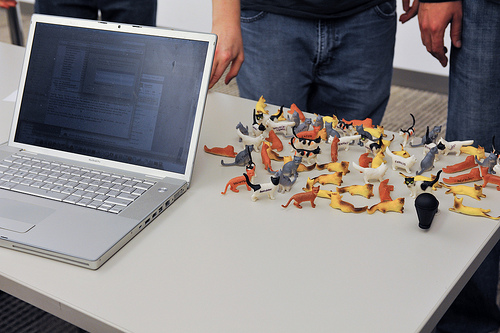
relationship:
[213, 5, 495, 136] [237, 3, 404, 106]
two people wearing jeans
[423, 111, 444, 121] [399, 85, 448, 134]
patterned tan and brown rug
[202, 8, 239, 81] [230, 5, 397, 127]
hands on side of jeans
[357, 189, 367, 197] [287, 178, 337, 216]
yellow and brown cats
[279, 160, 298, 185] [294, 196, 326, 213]
grey cat sitting on hind legs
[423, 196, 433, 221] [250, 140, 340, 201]
black and white cat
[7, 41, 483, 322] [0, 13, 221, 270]
table holding computer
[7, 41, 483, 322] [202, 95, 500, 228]
table holding cat figurines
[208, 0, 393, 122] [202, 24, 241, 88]
man with hands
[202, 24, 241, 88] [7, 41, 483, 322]
hands on table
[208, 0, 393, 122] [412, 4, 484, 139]
man standing beside man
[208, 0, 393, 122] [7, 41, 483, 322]
man standing behind table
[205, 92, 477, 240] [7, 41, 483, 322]
cat figurines on top of table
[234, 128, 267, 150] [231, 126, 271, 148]
figurine with fur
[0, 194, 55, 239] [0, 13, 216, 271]
mousepad on computer